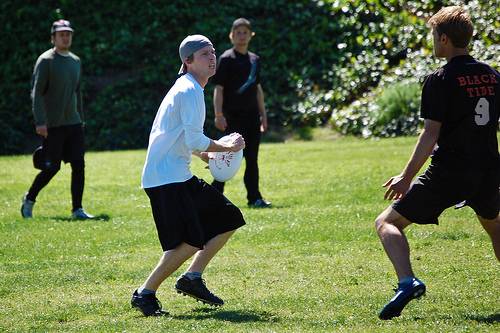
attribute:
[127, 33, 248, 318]
man — playing, young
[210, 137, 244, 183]
ball — white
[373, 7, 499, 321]
opponent — guarding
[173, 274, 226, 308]
sneaker — black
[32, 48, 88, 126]
shirt — green, long sleeved, long sleeve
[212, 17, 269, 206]
spectator — dressed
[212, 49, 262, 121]
shirt — black, striped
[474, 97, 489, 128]
number — white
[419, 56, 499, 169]
shirt — black, red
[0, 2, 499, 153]
trees — green, leaves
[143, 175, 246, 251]
shorts — black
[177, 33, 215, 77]
hat — gray, backwrads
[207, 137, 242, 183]
frisbee — white, game, red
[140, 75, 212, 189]
shirt — white, long sleeve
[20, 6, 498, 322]
men — playing, young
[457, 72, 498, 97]
lettering — red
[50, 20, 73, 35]
hat — forwards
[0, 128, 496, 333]
field — large, grassy, green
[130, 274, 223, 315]
cleats — pair, black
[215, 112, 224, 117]
armband — orange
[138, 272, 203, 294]
socks — gray